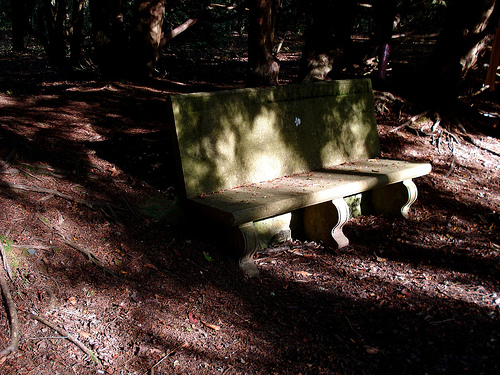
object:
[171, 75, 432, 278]
bench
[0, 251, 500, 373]
dry leaves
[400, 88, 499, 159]
roots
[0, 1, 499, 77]
trees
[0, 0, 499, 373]
woods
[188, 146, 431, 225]
fallen leaves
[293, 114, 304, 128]
spot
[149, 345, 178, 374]
twigs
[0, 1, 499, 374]
shadows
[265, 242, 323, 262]
stick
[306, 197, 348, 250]
legs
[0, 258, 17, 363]
roots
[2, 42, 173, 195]
foliage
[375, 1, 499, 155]
forest floor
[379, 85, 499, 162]
rocks and dirt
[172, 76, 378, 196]
moss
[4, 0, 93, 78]
background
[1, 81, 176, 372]
rotting leaves